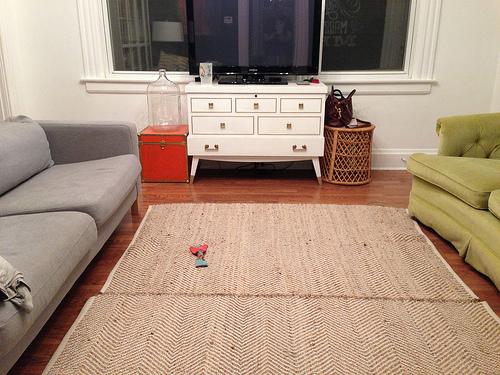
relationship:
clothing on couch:
[0, 256, 39, 313] [0, 112, 144, 373]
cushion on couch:
[0, 154, 140, 227] [32, 132, 120, 325]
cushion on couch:
[0, 210, 98, 361] [32, 132, 120, 325]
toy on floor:
[186, 240, 214, 268] [145, 180, 408, 207]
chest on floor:
[135, 122, 190, 185] [11, 167, 498, 373]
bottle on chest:
[131, 72, 195, 133] [139, 124, 190, 183]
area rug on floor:
[42, 202, 499, 374] [11, 167, 498, 373]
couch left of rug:
[0, 113, 145, 375] [101, 201, 480, 301]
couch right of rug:
[404, 111, 498, 291] [101, 193, 476, 306]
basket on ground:
[322, 117, 377, 186] [138, 178, 410, 373]